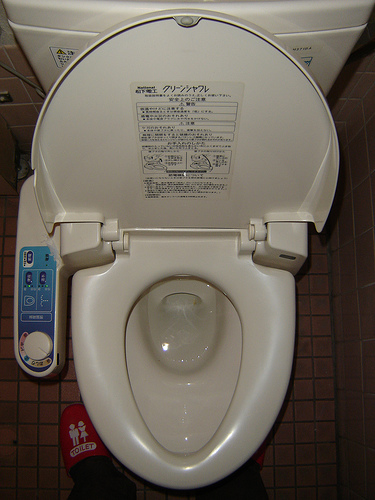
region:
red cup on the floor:
[55, 399, 95, 468]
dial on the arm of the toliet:
[23, 330, 52, 364]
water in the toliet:
[159, 324, 202, 353]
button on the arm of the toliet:
[20, 249, 36, 268]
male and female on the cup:
[63, 419, 89, 444]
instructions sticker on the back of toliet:
[125, 74, 240, 206]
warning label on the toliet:
[48, 43, 71, 59]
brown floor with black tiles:
[290, 413, 315, 455]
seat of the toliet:
[244, 345, 278, 400]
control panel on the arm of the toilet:
[16, 247, 61, 376]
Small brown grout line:
[314, 394, 331, 405]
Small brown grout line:
[315, 416, 331, 428]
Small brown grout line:
[318, 436, 328, 447]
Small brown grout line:
[308, 379, 318, 427]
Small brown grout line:
[272, 456, 299, 477]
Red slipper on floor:
[47, 407, 110, 498]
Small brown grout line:
[11, 375, 55, 386]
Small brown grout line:
[6, 394, 59, 412]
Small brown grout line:
[6, 413, 54, 432]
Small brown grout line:
[7, 435, 57, 455]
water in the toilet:
[172, 317, 204, 355]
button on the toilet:
[22, 249, 34, 267]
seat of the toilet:
[78, 287, 121, 355]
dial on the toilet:
[23, 330, 54, 368]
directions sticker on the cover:
[129, 77, 240, 202]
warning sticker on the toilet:
[52, 43, 67, 59]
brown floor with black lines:
[10, 416, 41, 476]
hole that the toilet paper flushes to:
[163, 292, 203, 313]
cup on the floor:
[56, 398, 103, 473]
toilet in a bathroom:
[7, 1, 349, 497]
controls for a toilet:
[17, 239, 62, 382]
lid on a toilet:
[28, 10, 343, 243]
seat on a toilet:
[76, 235, 298, 496]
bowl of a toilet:
[110, 280, 254, 457]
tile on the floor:
[281, 318, 343, 498]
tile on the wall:
[330, 223, 368, 412]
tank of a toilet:
[2, 3, 373, 75]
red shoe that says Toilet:
[50, 402, 105, 470]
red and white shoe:
[54, 397, 105, 470]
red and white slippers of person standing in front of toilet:
[49, 407, 264, 473]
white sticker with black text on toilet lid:
[131, 81, 242, 199]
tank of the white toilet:
[9, 5, 362, 116]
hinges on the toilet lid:
[99, 217, 264, 263]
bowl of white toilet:
[140, 287, 241, 447]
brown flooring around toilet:
[5, 187, 335, 494]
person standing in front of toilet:
[45, 401, 294, 498]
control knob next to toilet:
[19, 330, 49, 360]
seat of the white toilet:
[78, 235, 289, 487]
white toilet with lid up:
[10, 6, 368, 493]